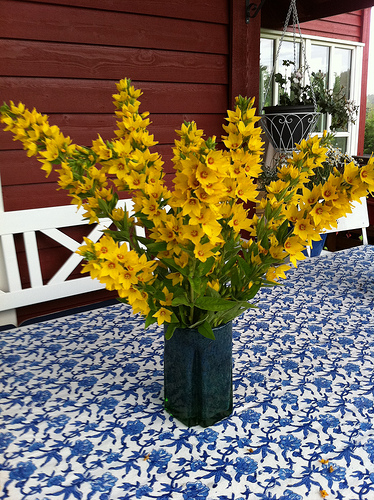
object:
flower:
[123, 170, 145, 192]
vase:
[163, 320, 233, 429]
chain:
[292, 2, 317, 112]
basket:
[255, 111, 323, 166]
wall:
[0, 3, 232, 214]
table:
[0, 248, 373, 500]